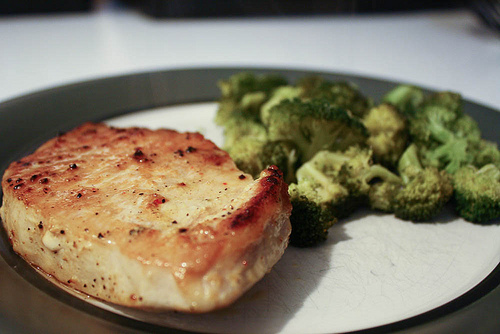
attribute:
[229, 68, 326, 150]
veggies — green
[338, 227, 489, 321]
plate — round, white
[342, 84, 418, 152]
veggies — green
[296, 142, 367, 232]
veggies — green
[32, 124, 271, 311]
fish — baked, seasoned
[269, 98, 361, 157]
broccoli — steamed, cooked, dry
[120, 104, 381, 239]
food — cooked, plated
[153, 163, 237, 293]
meat — cooked, grilled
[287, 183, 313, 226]
floret — cooked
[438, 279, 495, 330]
rim — black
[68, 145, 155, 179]
seasoning — black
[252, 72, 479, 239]
food — green, plated